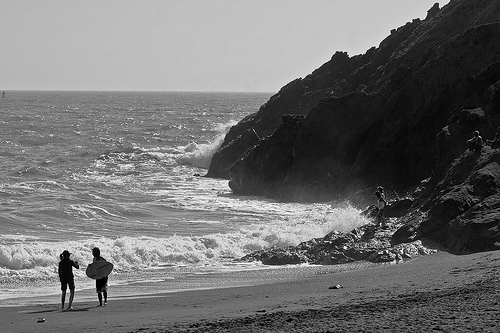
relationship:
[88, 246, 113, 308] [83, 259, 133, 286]
man holding surfboard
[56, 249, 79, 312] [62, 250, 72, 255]
people wearing cap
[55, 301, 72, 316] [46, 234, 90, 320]
foot of woman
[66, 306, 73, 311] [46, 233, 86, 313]
foot of woman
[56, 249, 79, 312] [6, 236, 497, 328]
people on beach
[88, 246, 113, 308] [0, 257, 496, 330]
man on beach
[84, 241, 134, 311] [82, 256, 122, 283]
man holding board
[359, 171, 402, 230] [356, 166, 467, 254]
man on rocks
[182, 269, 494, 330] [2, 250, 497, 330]
tracks in sand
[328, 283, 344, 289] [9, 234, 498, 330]
trash on sand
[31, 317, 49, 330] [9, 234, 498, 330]
trash on sand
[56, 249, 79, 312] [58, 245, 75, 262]
people wearing cap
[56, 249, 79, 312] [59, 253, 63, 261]
people wearing ponytail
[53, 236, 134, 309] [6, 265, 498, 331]
people on beach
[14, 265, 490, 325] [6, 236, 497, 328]
sand on beach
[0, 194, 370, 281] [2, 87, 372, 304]
waves of water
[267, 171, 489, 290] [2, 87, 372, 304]
rocks next to water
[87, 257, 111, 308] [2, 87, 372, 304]
body of water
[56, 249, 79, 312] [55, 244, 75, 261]
people wearing hat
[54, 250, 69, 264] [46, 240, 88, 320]
ponytail of woman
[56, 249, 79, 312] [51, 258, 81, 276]
people wearing shirt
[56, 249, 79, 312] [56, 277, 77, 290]
people wearing pant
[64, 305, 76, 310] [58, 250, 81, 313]
foot of woman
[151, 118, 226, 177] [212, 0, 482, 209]
waves crashing on rocks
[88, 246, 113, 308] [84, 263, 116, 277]
man holding surfboard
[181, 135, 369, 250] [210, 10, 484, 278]
waves crashing into rocks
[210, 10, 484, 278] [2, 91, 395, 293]
rocks alongside water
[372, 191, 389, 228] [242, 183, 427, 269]
man standing on rocks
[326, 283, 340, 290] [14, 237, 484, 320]
trash laying on beach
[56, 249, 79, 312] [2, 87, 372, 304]
people next to water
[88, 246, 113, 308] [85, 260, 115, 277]
man with board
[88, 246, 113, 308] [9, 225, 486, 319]
man on beach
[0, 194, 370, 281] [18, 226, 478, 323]
waves breaking on shore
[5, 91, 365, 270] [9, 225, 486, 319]
body beyond beach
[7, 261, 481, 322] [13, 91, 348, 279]
beach near water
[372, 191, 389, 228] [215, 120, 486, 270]
man standing on shore